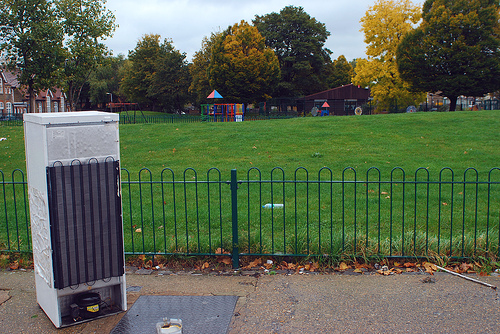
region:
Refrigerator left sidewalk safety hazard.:
[14, 105, 137, 328]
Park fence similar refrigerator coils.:
[63, 157, 221, 245]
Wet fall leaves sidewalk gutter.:
[139, 253, 461, 285]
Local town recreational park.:
[147, 109, 499, 224]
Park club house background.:
[298, 84, 385, 127]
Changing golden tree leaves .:
[362, 2, 423, 109]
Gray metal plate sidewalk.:
[109, 290, 252, 331]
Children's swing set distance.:
[98, 93, 163, 133]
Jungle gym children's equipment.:
[196, 89, 246, 126]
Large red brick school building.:
[1, 64, 85, 116]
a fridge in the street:
[25, 114, 127, 331]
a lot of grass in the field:
[196, 121, 496, 162]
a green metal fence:
[234, 168, 498, 260]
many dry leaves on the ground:
[246, 258, 478, 276]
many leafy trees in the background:
[21, 40, 471, 81]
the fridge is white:
[24, 118, 126, 317]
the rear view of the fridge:
[46, 117, 125, 313]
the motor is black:
[71, 296, 104, 319]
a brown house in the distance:
[312, 84, 367, 119]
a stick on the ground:
[431, 262, 497, 304]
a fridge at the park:
[23, 35, 363, 299]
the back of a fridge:
[25, 93, 139, 228]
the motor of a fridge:
[26, 271, 147, 327]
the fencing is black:
[142, 140, 250, 246]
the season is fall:
[174, 3, 313, 141]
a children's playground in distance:
[145, 8, 348, 141]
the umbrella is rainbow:
[194, 45, 279, 126]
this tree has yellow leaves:
[336, 8, 465, 137]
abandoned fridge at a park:
[34, 36, 485, 308]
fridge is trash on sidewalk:
[14, 13, 467, 317]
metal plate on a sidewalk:
[109, 283, 244, 333]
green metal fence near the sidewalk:
[1, 162, 499, 276]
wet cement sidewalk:
[1, 260, 499, 332]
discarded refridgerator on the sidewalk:
[21, 105, 133, 324]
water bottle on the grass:
[257, 195, 287, 212]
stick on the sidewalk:
[421, 255, 499, 303]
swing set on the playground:
[102, 95, 151, 125]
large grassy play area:
[0, 112, 498, 264]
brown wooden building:
[296, 77, 388, 122]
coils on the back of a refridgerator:
[41, 153, 132, 293]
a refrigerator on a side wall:
[21, 109, 128, 328]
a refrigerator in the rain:
[23, 102, 131, 329]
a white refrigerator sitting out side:
[22, 106, 127, 332]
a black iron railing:
[198, 167, 493, 255]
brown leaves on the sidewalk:
[271, 260, 489, 277]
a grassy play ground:
[117, 98, 423, 158]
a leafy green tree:
[398, 0, 495, 115]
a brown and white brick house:
[0, 60, 65, 115]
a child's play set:
[194, 102, 244, 124]